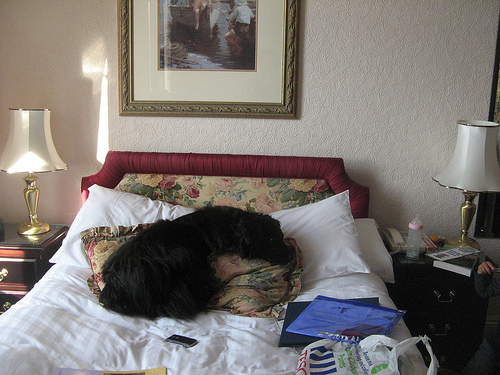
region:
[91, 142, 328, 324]
a dog in bed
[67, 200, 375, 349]
a black dog in bed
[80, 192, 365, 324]
a dog sleeping in bed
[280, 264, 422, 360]
a small pack of shirt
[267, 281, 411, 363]
a shirt placed in bed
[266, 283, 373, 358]
a shirt placed before dog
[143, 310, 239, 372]
a mobile phone in bed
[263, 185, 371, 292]
a white pillow in bed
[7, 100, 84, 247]
a small bed lamp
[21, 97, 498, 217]
two bed lamps and chair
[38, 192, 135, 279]
white pillow on a bed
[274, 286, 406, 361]
two records on a bed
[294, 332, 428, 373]
plastic bag on a bed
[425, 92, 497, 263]
gold lamp with a white shade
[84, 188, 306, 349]
black dog laying on a pillow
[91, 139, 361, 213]
floral headboard on a bed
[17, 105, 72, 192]
sunlight shining on a lamp shade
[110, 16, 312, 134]
art work hanging on a wall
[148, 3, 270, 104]
artwork framed in a gold frame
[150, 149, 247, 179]
maroon border on a headboard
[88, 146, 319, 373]
black dog laying on bed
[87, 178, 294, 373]
black dog laying on floral pillow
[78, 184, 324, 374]
black dog laying on white sheets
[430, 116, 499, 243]
gold side table lamp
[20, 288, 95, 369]
white stripped comforter set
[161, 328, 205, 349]
black cell phone on bed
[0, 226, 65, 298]
cherry bedroom night stand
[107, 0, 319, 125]
large picture over bed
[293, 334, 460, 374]
white store shopping bag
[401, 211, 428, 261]
pink topped baby bottle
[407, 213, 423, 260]
A plastic baby bottle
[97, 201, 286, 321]
A large black dog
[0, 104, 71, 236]
A white and gold lamp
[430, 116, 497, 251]
A white and gold lamp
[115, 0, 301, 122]
A picture on the wall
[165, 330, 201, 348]
a cellphone on a bed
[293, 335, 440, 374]
A white plastic bag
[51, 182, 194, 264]
A large white pillow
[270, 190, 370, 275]
A large white pillow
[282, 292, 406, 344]
a blue plastic bag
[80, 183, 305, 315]
One black dog laying on bed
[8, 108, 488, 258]
Two large bedroom lamps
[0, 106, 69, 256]
One large bedroom lamp outlined in gold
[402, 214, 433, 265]
One clear baby bottle with pink ring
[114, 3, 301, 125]
One large picture tacked on wall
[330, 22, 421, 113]
Tan background painted wall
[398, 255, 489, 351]
One dark wooded small dresser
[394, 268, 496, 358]
Small dark wood dresser with 2 gold handles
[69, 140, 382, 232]
Large bed with red outlined headboard